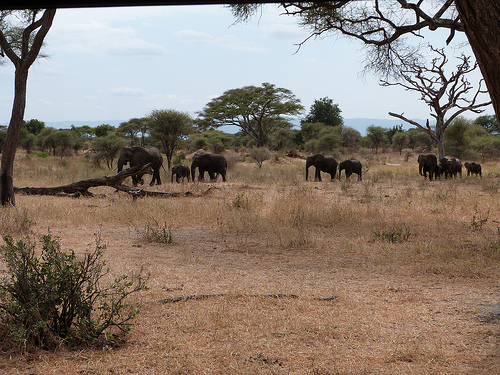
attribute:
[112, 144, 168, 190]
elephant — adult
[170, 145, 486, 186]
group — walking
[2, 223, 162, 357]
bush — green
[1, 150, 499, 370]
ground — dry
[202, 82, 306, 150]
tree — large, tall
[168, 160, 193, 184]
elephant — baby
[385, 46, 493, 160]
tree — dead, bare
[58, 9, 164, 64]
cloud — fluffy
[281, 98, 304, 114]
leaves — green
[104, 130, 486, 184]
elephants — walking, together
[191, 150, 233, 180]
elephant — mother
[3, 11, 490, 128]
sky — blue